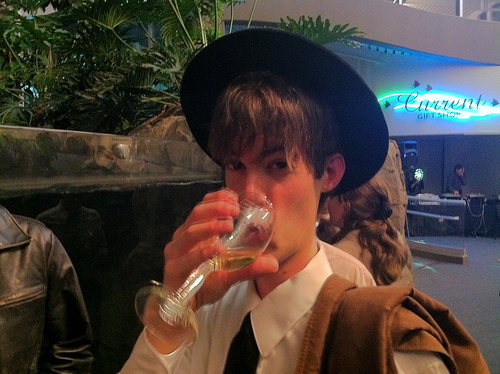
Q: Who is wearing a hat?
A: The young man.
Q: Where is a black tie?
A: Around guy's neck.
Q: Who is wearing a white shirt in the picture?
A: Guy.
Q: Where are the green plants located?
A: Planter.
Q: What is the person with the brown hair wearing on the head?
A: Hat.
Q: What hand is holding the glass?
A: Right.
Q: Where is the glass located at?
A: Mouth.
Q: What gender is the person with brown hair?
A: Male.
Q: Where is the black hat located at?
A: Head.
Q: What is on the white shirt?
A: Tie.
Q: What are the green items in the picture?
A: Plants.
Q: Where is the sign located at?
A: Wall.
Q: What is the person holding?
A: A glass.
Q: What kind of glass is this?
A: A wine glass.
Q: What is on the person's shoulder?
A: A brown jacket.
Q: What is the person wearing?
A: A white shirt.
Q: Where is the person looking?
A: At the camera.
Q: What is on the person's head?
A: A hat.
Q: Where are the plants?
A: Over the rocks.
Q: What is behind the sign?
A: Neon lights.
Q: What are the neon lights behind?
A: A sign.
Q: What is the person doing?
A: Drinking.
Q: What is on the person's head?
A: Hat.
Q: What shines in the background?
A: Sign.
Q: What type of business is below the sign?
A: Gift shop.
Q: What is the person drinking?
A: Wine.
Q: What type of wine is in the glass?
A: White.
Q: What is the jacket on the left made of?
A: Leather.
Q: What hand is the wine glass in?
A: Right.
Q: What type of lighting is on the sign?
A: Neon.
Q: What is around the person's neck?
A: Necktie.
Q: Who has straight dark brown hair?
A: The person.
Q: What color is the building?
A: White.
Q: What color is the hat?
A: Black.